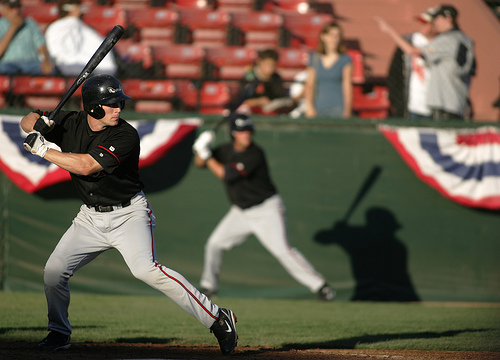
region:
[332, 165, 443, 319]
shadow of baseball player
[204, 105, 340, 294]
blurry baseball player in the background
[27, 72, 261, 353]
baseball player ready to bat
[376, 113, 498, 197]
blurry patriotic banner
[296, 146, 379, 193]
dark green barrier from stands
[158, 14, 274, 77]
red seats in stands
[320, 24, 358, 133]
woman with a grey shirt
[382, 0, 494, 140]
man pointing to his left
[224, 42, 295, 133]
young man sitting down with a black shirt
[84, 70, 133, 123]
black shiny baseball helemt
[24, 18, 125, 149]
a black bat in a man's hands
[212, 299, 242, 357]
a black Nike cleat on a man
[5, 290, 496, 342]
grass on a baseball field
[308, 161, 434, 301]
the shadow of a man with a bat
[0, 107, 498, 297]
a green wall at a baseball field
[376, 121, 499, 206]
a red, white, and blue banner on a wall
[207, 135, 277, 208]
a black shirt on a man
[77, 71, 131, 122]
a helmet on a man's head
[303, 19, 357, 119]
a woman in a blue dress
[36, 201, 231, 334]
white pants on a man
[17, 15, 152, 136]
the baseball bat is black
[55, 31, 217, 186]
the baseball bat is black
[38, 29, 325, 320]
players are waiting to hit the ball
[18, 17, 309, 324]
players are holding bats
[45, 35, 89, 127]
the bat is black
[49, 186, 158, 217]
the man is wearing a belt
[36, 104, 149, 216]
the man is wearing a shirt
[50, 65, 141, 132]
player is wearing a helmet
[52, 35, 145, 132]
the helmet is black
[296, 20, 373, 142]
a woman is standing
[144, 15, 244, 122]
the chairs are red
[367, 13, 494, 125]
two people are talking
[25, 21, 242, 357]
A man playing baseball.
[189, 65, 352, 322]
A man playing baseball.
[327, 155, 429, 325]
Shadow of a man batting.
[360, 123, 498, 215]
Red, white, and blue bunting.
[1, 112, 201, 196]
Red, white, and blue bunting.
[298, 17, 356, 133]
A woman watching the baseball game.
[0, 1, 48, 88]
A man watching the baeball game.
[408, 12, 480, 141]
A man explaining something away from the game.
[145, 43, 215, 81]
An empty staduim seat.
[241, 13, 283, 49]
An empty stadium seat.